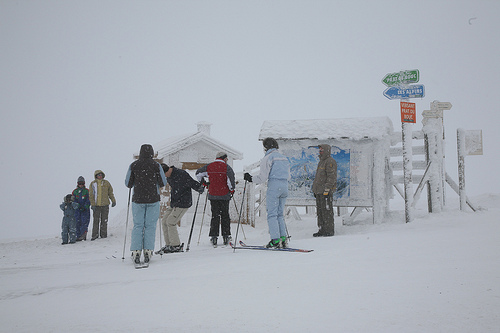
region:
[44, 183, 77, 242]
this is a person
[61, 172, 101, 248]
this is a person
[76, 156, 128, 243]
this is a person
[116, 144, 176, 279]
this is a person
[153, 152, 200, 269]
this is a person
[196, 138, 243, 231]
this is a person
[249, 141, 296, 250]
this is a person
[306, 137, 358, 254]
this is a person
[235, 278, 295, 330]
this is white snow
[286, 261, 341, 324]
this is white snow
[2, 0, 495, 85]
the sky is gray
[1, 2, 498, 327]
a complete white out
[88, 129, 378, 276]
the people on the snow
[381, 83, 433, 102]
blue sign on the post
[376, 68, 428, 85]
green sign on the pole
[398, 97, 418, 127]
red sign on the pole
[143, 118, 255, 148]
snow on the roof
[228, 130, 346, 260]
the man on the skis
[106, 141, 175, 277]
the person on the skis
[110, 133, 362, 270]
the people are skiing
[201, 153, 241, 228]
a man in a red jacket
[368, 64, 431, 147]
more than one directional signs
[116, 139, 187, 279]
a person in blue pants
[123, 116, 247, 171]
a building beyond people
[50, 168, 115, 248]
a group of people standing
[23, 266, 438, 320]
lots of snow on the ground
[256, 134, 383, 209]
a sign on a building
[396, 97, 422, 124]
a red sign with white lettering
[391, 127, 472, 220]
a fence covered in snow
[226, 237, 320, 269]
a pair of skis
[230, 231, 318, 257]
Woman on skis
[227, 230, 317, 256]
Woman is on skis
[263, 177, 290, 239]
Woman wearing pants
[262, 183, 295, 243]
Woman is wearing pants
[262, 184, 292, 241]
Woman wearing blue pants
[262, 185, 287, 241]
Woman is wearing blue pants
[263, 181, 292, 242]
Woman wearing light blue pants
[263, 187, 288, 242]
Woman is wearing light blue pants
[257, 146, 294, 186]
Woman wearing a light blue jacket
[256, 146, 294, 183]
Woman is wearing a light blue jacket